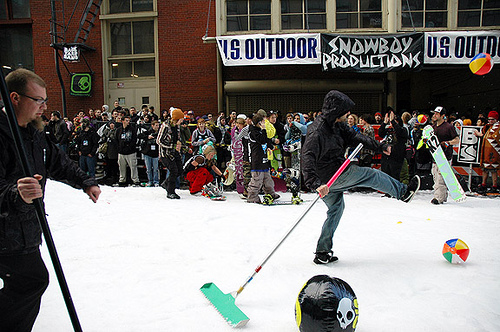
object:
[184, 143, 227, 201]
man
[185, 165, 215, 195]
red pants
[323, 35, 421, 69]
letters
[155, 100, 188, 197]
man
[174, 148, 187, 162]
hat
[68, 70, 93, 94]
sign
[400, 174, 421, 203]
foot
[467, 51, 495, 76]
ball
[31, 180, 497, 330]
snow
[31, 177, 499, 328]
ground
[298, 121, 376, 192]
jacket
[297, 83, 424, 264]
man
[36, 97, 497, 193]
crowd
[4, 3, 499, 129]
building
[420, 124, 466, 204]
snowboard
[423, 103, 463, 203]
man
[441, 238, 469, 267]
beach ball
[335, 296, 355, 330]
skull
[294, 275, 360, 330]
ball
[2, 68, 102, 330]
man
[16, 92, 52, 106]
glasses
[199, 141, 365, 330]
shovel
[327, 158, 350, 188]
tape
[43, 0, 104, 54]
ladder